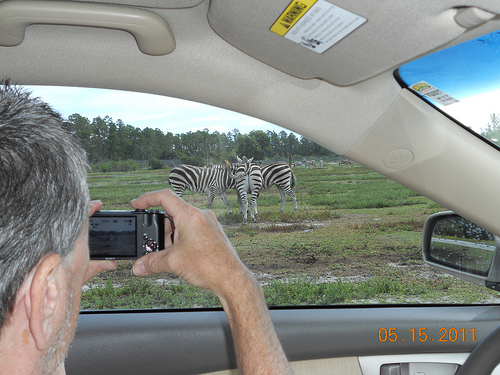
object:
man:
[38, 99, 176, 146]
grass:
[304, 180, 396, 256]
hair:
[0, 88, 89, 253]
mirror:
[416, 205, 498, 286]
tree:
[92, 114, 180, 159]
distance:
[92, 99, 243, 162]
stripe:
[179, 166, 215, 190]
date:
[368, 314, 484, 351]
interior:
[81, 312, 499, 374]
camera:
[81, 203, 176, 264]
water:
[322, 276, 335, 281]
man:
[0, 81, 300, 374]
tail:
[227, 163, 252, 180]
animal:
[224, 155, 264, 226]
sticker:
[409, 78, 461, 109]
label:
[265, 1, 370, 58]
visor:
[202, 0, 488, 92]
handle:
[0, 0, 178, 59]